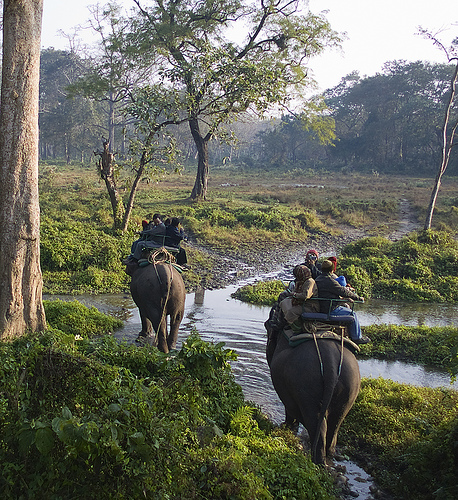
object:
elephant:
[130, 257, 185, 353]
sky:
[41, 2, 457, 115]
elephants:
[130, 243, 360, 465]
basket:
[302, 297, 354, 322]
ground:
[363, 158, 392, 175]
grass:
[208, 193, 303, 237]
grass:
[149, 419, 237, 490]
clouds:
[36, 0, 456, 113]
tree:
[102, 0, 327, 205]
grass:
[192, 357, 283, 434]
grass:
[378, 227, 450, 303]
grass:
[345, 381, 454, 491]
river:
[49, 193, 447, 493]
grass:
[0, 295, 352, 499]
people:
[122, 213, 190, 267]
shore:
[3, 153, 456, 496]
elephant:
[270, 320, 361, 466]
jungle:
[2, 0, 457, 494]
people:
[267, 249, 368, 344]